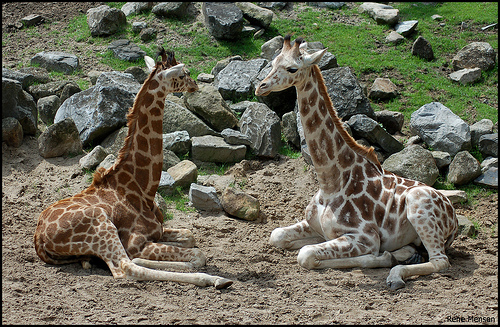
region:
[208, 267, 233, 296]
a foot of a giraffe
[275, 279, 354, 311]
dirt on the ground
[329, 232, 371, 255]
spots on the leg of a giraffe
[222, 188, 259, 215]
a brown and grey rock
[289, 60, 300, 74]
the left eye of a giraffe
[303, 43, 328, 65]
left ear of a giraffe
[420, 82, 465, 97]
green grass and dirt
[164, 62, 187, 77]
eight ear of a giraffe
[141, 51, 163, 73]
left ear of a giraffe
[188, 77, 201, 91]
nose of a giraffe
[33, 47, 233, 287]
a giraffe laying down on the left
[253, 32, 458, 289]
a giraffe laying down on the right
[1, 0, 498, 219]
rocks behind the giraffes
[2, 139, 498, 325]
a sandy area the giraffes are laying on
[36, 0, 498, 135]
a grassy area behind the giraffe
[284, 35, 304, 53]
the horns of the right giraffe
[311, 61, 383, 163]
the mane of the right giraffe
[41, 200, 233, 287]
the hind leg of the left giraffe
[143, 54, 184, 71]
the ears of the left giraffe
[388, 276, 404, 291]
the right giraffe's hoof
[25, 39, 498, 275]
The giraffes are sitting down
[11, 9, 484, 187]
Rocks are all over the ground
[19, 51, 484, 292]
The giraffes have long legs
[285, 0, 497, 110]
The grass is green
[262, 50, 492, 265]
This giraffe is white with brown spots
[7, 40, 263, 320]
This giraffe is light brown with dark brown spots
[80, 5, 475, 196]
The giraffes have hair on their necks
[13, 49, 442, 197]
The rocks are large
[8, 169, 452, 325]
The giraffes are sitting in dirt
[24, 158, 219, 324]
The giraffe is sitting on its tail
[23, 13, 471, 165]
rocks and green grass on hill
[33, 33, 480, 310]
two giraffes sitting on ground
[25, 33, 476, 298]
two giraffes sitting on sand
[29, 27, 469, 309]
two giraffes facing each other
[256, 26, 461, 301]
giraffe with a long neck and knobby knees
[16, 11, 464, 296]
large stones and sand on ground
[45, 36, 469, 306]
two mammals facing each other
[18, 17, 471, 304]
two animals sitting comfortably on ground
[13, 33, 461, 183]
pile of rocks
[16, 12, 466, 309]
two long necks and eight knobby knees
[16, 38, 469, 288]
Two giraffes sitting on dirt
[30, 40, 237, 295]
A giraffe facing right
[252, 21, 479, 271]
A giraffe facing left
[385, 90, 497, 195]
A set of rocks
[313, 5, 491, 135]
A small amount of green grass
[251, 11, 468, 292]
A white and brown giraffe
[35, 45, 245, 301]
A yellow and brown giraffe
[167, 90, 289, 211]
Rocks in between two giraffes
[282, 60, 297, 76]
The left eye of a giraffe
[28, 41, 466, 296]
A pair of giraffes sitting down